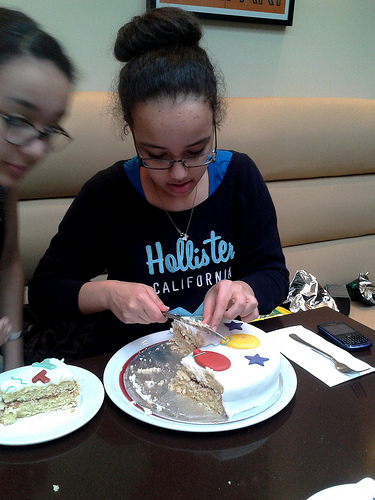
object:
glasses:
[131, 125, 216, 170]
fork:
[288, 332, 367, 376]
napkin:
[265, 324, 375, 388]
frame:
[145, 0, 295, 26]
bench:
[16, 91, 375, 332]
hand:
[201, 277, 259, 332]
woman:
[0, 6, 74, 371]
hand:
[108, 279, 170, 325]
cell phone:
[317, 319, 372, 351]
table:
[0, 307, 375, 499]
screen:
[323, 323, 356, 336]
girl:
[27, 6, 291, 342]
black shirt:
[27, 150, 288, 323]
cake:
[169, 318, 283, 423]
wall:
[0, 0, 375, 98]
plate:
[103, 329, 298, 432]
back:
[0, 90, 374, 285]